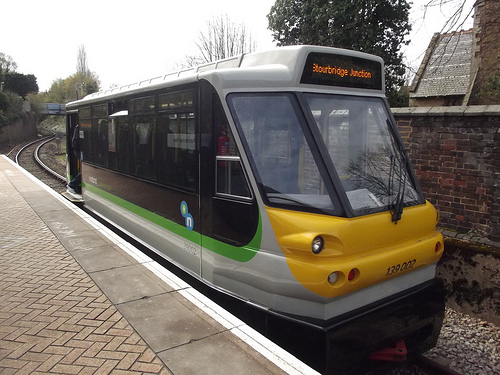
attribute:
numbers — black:
[375, 248, 439, 294]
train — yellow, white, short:
[49, 40, 459, 361]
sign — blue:
[175, 195, 200, 221]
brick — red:
[1, 174, 168, 372]